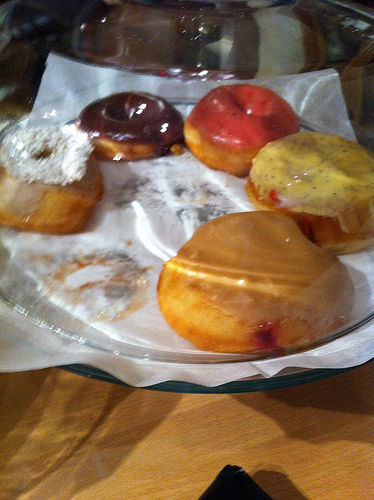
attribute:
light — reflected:
[133, 99, 147, 118]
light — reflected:
[157, 121, 172, 135]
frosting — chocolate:
[77, 87, 178, 141]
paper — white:
[6, 41, 372, 389]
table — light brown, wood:
[12, 344, 372, 499]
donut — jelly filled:
[139, 181, 372, 389]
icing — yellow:
[238, 112, 372, 228]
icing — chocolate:
[68, 73, 193, 181]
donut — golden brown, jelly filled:
[160, 204, 362, 358]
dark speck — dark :
[310, 183, 323, 193]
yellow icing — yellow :
[252, 127, 372, 226]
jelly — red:
[246, 314, 284, 348]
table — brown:
[279, 437, 340, 471]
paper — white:
[194, 362, 225, 379]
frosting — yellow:
[283, 153, 315, 163]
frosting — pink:
[216, 110, 235, 126]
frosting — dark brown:
[132, 116, 152, 130]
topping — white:
[58, 139, 81, 164]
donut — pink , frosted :
[175, 79, 304, 172]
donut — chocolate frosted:
[71, 88, 189, 166]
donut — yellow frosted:
[240, 124, 372, 258]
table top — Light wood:
[4, 360, 370, 497]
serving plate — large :
[41, 348, 362, 394]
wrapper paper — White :
[3, 46, 372, 376]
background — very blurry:
[20, 0, 372, 129]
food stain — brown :
[27, 242, 167, 329]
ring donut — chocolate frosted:
[73, 86, 195, 167]